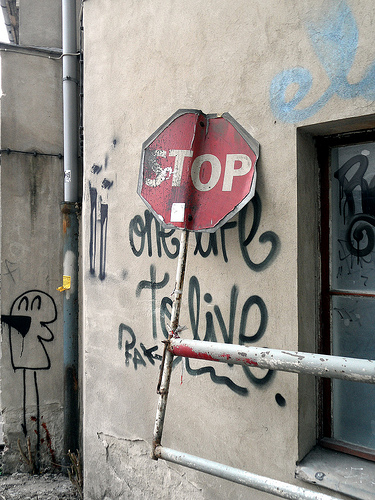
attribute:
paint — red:
[170, 345, 258, 369]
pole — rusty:
[145, 227, 192, 462]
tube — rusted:
[161, 338, 372, 385]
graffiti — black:
[3, 284, 59, 457]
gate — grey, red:
[148, 336, 373, 498]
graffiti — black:
[324, 158, 373, 240]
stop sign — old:
[134, 99, 264, 245]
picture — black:
[0, 294, 73, 406]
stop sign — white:
[130, 125, 264, 464]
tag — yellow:
[56, 262, 73, 294]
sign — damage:
[142, 122, 274, 247]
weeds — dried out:
[14, 432, 82, 497]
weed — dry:
[25, 436, 33, 472]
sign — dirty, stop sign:
[137, 109, 261, 233]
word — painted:
[126, 203, 188, 263]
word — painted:
[190, 182, 284, 272]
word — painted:
[132, 261, 179, 341]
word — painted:
[181, 271, 287, 396]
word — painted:
[115, 316, 161, 372]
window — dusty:
[317, 128, 374, 464]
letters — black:
[116, 190, 286, 406]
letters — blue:
[269, 0, 373, 124]